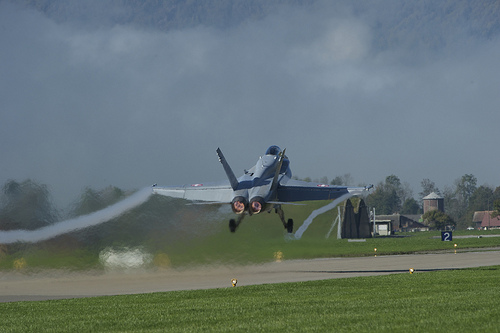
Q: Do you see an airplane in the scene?
A: Yes, there is an airplane.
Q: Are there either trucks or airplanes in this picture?
A: Yes, there is an airplane.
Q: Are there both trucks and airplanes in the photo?
A: No, there is an airplane but no trucks.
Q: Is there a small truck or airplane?
A: Yes, there is a small airplane.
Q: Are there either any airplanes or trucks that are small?
A: Yes, the airplane is small.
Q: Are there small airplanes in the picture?
A: Yes, there is a small airplane.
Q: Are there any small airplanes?
A: Yes, there is a small airplane.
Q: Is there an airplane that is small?
A: Yes, there is an airplane that is small.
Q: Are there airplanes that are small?
A: Yes, there is an airplane that is small.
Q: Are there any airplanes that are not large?
A: Yes, there is a small airplane.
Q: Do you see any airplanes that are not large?
A: Yes, there is a small airplane.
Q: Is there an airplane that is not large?
A: Yes, there is a small airplane.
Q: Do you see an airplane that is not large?
A: Yes, there is a small airplane.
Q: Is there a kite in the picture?
A: No, there are no kites.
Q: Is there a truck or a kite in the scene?
A: No, there are no kites or trucks.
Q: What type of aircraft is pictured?
A: The aircraft is an airplane.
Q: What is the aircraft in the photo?
A: The aircraft is an airplane.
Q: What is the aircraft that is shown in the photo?
A: The aircraft is an airplane.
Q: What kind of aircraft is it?
A: The aircraft is an airplane.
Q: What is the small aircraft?
A: The aircraft is an airplane.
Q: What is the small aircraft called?
A: The aircraft is an airplane.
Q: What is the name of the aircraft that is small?
A: The aircraft is an airplane.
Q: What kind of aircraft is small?
A: The aircraft is an airplane.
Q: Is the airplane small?
A: Yes, the airplane is small.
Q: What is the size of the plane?
A: The plane is small.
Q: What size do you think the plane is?
A: The plane is small.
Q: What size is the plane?
A: The plane is small.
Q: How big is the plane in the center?
A: The plane is small.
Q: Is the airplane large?
A: No, the airplane is small.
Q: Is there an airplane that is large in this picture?
A: No, there is an airplane but it is small.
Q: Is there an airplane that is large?
A: No, there is an airplane but it is small.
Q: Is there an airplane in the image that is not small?
A: No, there is an airplane but it is small.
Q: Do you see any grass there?
A: Yes, there is grass.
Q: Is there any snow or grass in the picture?
A: Yes, there is grass.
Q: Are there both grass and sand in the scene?
A: No, there is grass but no sand.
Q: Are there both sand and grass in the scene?
A: No, there is grass but no sand.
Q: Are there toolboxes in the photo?
A: No, there are no toolboxes.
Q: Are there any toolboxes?
A: No, there are no toolboxes.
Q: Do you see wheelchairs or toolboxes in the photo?
A: No, there are no toolboxes or wheelchairs.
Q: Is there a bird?
A: No, there are no birds.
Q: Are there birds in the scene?
A: No, there are no birds.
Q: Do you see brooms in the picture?
A: No, there are no brooms.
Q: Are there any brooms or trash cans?
A: No, there are no brooms or trash cans.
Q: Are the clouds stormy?
A: Yes, the clouds are stormy.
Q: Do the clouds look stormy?
A: Yes, the clouds are stormy.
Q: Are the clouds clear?
A: No, the clouds are stormy.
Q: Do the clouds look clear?
A: No, the clouds are stormy.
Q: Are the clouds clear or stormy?
A: The clouds are stormy.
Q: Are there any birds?
A: No, there are no birds.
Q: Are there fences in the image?
A: No, there are no fences.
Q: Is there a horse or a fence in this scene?
A: No, there are no fences or horses.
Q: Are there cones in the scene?
A: No, there are no cones.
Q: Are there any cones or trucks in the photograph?
A: No, there are no cones or trucks.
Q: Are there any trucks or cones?
A: No, there are no cones or trucks.